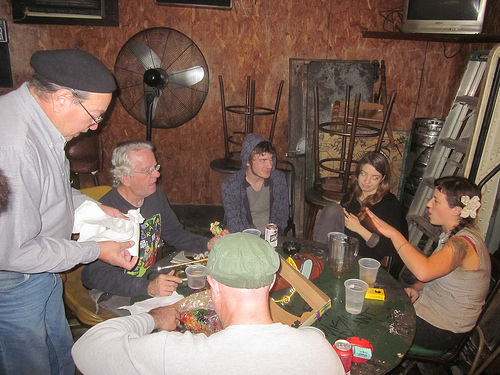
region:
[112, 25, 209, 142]
a black fan with silver blades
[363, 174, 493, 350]
a woman with a flower in her hair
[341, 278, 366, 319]
a clear plastic glass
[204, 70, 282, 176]
a stool upside down on a table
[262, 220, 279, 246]
an aluminum can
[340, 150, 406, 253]
a woman wearing a black shirt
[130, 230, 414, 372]
a green table with writing on it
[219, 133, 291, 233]
a man wearing a gray jacket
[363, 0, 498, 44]
a TV on a shelf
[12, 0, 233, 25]
two pictures on the wall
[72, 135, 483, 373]
people sitting at table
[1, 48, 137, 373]
standing man in beret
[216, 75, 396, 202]
two upside down bar stools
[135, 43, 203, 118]
metal blades of fan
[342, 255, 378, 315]
two plastic cups on table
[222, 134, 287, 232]
man with hood on head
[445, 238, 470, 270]
tattoo on woman's arm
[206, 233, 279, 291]
green hat on head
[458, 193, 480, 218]
flower in woman's hair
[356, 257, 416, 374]
edge of round table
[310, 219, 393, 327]
cups on the table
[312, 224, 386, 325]
cups on the table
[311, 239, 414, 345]
cups on the table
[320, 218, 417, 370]
cups on the table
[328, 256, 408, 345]
cups on the table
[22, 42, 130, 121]
the berret is black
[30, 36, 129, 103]
the berret is black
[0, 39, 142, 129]
the berret is black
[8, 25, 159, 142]
the berret is black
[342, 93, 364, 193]
brown wooden stool leg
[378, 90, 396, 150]
brown wooden stool leg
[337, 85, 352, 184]
brown wooden stool leg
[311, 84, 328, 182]
brown wooden stool leg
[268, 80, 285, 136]
brown wooden stool leg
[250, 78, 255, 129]
brown wooden stool leg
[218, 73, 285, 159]
brown wooden stool legs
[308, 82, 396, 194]
brown wooden stool legs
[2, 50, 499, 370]
a group of people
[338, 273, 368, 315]
clear plastic cup on the table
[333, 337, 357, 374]
red can on the table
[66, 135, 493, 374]
five people sitting around a table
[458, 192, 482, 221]
flower in the hair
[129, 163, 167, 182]
glasses on the face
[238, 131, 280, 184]
hood is up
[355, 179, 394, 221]
hair laying over the shoulder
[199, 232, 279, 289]
green cap on the head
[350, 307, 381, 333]
writing on the table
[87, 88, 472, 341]
people at the table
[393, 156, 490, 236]
head of the lady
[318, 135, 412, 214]
girl looking at other girl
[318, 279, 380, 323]
clear cup on table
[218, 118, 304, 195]
man with a hood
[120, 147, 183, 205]
glasses on man's face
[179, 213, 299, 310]
hat on the man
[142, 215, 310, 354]
back of the man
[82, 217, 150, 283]
hand of the man